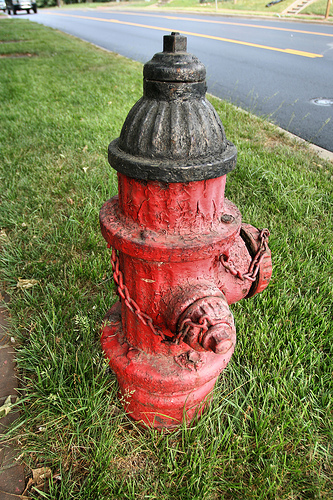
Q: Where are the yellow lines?
A: Road.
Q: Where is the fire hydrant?
A: Grass.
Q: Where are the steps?
A: Top right corner.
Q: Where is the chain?
A: Fire hydrant.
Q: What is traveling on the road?
A: Vehicle.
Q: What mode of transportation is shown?
A: Truck.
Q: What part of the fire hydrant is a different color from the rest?
A: Cap.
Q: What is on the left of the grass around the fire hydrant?
A: Sidewalk.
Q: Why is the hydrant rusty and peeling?
A: The paint is old.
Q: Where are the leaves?
A: On the ground.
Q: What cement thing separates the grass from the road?
A: Curb.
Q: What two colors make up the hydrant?
A: Red and black.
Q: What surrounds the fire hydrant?
A: Grass.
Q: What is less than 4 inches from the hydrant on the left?
A: A sidewalk.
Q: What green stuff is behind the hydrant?
A: Grass.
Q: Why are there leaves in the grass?
A: They fell off the trees.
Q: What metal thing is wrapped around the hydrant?
A: Chain.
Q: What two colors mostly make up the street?
A: Gray and yellow.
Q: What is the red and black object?
A: Fire hydrant.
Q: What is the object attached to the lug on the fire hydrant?
A: Chain.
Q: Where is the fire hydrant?
A: Grass.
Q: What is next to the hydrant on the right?
A: Street.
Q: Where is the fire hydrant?
A: Next to curb.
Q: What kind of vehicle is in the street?
A: Car.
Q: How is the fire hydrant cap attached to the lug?
A: Chain.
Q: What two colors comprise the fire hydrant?
A: Red and black.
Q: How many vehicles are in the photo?
A: One.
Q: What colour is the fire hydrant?
A: Red and black.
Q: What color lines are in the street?
A: Yellow.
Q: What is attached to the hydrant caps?
A: A chain.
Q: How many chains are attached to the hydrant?
A: Two.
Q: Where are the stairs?
A: Across the street in the upper righthand corner.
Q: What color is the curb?
A: Beige.